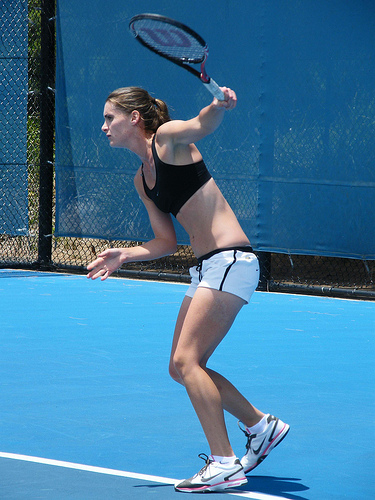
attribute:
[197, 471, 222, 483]
logo — nike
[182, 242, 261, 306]
shorts — white, black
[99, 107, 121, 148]
face — serious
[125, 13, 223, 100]
tennis racket — purple, black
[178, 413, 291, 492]
sneakers — black , white pink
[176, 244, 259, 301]
shorts — white , black 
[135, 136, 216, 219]
bra — black cotton sports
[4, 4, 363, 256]
tarp — blue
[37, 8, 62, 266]
pole — black metal fence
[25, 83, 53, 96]
hook — metal 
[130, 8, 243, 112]
racquet — tennis 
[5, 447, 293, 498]
line — white 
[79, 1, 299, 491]
player — tennis , female tennis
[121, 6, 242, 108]
racket — tennis 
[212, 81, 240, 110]
hand — woman's 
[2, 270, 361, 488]
court — tennis 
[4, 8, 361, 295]
fence — metal chain link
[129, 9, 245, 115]
racket — tennis 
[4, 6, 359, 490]
court — tennis , blue 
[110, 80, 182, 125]
hair — woman's 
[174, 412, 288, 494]
shoes — black, white 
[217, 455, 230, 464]
symbol — Nike 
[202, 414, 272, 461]
socks — her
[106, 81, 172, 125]
hair — brown ,  head full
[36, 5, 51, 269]
pipe — black 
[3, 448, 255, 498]
boundary — line marks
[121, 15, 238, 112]
tennis racket — held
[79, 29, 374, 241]
tarp — attached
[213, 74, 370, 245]
tarp — attached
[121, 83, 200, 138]
hair — tied back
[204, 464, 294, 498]
shadow — created